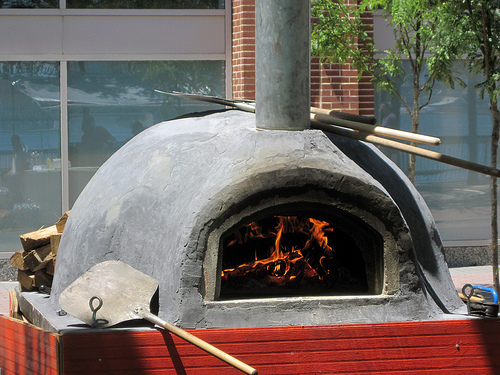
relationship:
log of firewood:
[18, 225, 57, 248] [12, 210, 70, 298]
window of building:
[67, 62, 230, 211] [2, 4, 494, 248]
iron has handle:
[465, 278, 498, 321] [469, 284, 497, 305]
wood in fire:
[231, 235, 294, 265] [244, 220, 357, 289]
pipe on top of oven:
[256, 0, 313, 130] [46, 2, 473, 321]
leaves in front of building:
[314, 3, 405, 79] [2, 4, 494, 248]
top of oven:
[172, 103, 395, 185] [46, 2, 473, 321]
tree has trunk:
[320, 7, 474, 218] [405, 26, 425, 196]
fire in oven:
[244, 220, 357, 289] [46, 2, 473, 321]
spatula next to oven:
[52, 253, 255, 373] [46, 2, 473, 321]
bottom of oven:
[3, 315, 499, 373] [46, 2, 473, 321]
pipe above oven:
[256, 0, 313, 130] [46, 2, 473, 321]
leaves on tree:
[314, 3, 405, 79] [320, 7, 474, 218]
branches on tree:
[399, 25, 442, 110] [320, 7, 474, 218]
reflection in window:
[71, 108, 117, 166] [67, 62, 230, 211]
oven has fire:
[46, 2, 473, 321] [244, 220, 357, 289]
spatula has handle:
[52, 253, 255, 373] [137, 309, 264, 374]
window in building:
[67, 62, 230, 211] [2, 4, 494, 248]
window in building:
[2, 63, 61, 265] [2, 4, 494, 248]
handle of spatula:
[137, 309, 264, 374] [52, 253, 255, 373]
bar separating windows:
[56, 59, 72, 220] [4, 59, 231, 251]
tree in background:
[320, 7, 474, 218] [232, 12, 499, 195]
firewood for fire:
[12, 210, 70, 298] [244, 220, 357, 289]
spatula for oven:
[52, 253, 255, 373] [46, 2, 473, 321]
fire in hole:
[244, 220, 357, 289] [210, 199, 395, 302]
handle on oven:
[82, 290, 108, 333] [46, 2, 473, 321]